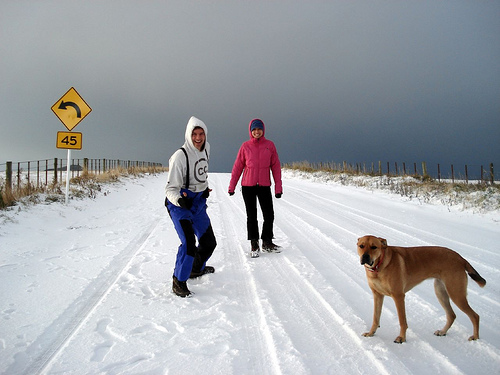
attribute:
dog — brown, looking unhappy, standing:
[356, 234, 488, 346]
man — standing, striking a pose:
[165, 114, 218, 298]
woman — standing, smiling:
[226, 117, 285, 258]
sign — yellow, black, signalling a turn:
[50, 85, 91, 130]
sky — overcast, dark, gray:
[2, 2, 499, 178]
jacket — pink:
[226, 117, 283, 196]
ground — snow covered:
[2, 169, 499, 375]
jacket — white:
[166, 116, 211, 208]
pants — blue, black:
[165, 188, 218, 282]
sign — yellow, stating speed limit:
[56, 130, 85, 150]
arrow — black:
[57, 99, 83, 119]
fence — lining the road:
[2, 157, 164, 209]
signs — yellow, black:
[50, 84, 92, 150]